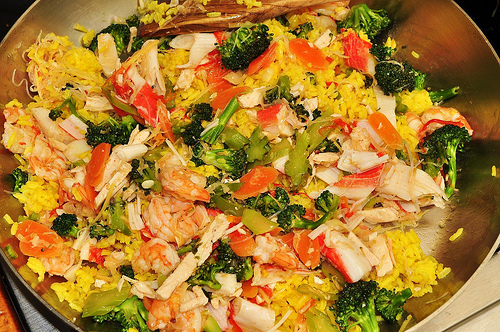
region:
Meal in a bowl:
[2, 4, 498, 324]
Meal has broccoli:
[9, 1, 497, 327]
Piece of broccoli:
[410, 114, 474, 201]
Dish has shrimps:
[11, 101, 313, 329]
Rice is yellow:
[388, 225, 454, 295]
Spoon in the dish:
[111, 0, 411, 42]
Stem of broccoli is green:
[273, 110, 325, 190]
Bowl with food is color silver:
[1, 1, 496, 327]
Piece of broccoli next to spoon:
[207, 15, 282, 75]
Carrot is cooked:
[76, 139, 116, 194]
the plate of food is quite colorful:
[22, 14, 497, 329]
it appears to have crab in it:
[124, 73, 176, 133]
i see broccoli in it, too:
[301, 268, 401, 327]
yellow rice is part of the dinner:
[357, 237, 447, 295]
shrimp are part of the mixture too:
[146, 160, 223, 254]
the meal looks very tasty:
[34, 25, 496, 330]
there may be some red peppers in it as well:
[222, 35, 358, 98]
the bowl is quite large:
[0, 6, 492, 330]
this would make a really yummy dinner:
[43, 65, 409, 287]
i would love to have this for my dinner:
[62, 9, 456, 321]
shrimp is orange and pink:
[146, 145, 215, 207]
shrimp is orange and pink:
[128, 182, 198, 243]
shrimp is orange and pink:
[120, 225, 178, 279]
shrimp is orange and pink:
[28, 135, 76, 190]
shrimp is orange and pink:
[133, 274, 211, 327]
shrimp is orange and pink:
[243, 222, 304, 287]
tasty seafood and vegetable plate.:
[12, 12, 455, 318]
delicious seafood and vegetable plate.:
[10, 7, 470, 317]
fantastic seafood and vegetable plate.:
[10, 12, 470, 317]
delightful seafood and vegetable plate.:
[7, 10, 472, 320]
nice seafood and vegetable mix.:
[20, 7, 475, 313]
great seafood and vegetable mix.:
[10, 16, 451, 311]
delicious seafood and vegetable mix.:
[30, 10, 475, 317]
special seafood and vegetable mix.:
[12, 11, 477, 318]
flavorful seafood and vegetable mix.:
[15, 10, 481, 321]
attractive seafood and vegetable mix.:
[10, 12, 475, 318]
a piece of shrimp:
[422, 100, 474, 127]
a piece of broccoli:
[334, 277, 387, 330]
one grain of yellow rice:
[443, 223, 467, 246]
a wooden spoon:
[129, 0, 378, 40]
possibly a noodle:
[7, 67, 40, 102]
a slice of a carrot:
[71, 122, 111, 199]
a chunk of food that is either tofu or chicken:
[153, 247, 199, 301]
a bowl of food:
[3, 3, 498, 330]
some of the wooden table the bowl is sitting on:
[0, 279, 22, 327]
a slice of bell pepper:
[240, 205, 280, 241]